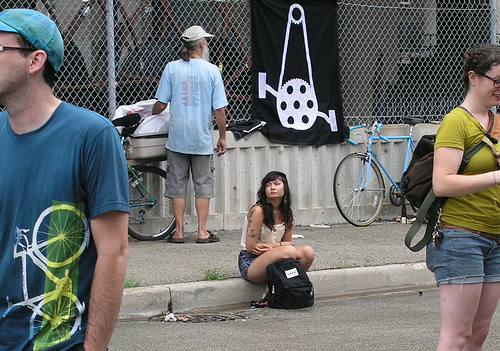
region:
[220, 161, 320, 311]
woman sitting on a curb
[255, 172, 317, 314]
black backpack in front of woman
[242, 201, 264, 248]
tattoos on woman's arm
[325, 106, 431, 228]
blue bicycle leaning against wall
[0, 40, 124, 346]
bicycle design on man's shirt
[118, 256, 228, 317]
weeds growing next to curb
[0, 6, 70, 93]
man wearing a blue cap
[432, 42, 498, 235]
woman wearing a green shirt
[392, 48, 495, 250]
woman wearing a backpack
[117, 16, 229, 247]
older man standing beside a bicycle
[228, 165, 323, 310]
woman sitting on curb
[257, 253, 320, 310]
black bag on street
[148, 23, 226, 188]
back of standing man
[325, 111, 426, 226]
blue bike against wall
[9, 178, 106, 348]
white bike on tee shirt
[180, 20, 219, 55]
hat on man's head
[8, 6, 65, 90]
blue hat on man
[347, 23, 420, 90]
metal of chain link fence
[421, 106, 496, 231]
green short sleeved shirt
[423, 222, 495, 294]
cut off blue jeans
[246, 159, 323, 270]
a person in the picture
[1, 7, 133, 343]
a person in the picture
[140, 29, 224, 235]
a person in the picture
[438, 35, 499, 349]
a person in the picture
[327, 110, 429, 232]
a bike in the picture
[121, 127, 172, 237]
a bike in the picture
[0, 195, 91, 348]
a bike in the picture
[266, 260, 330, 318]
a black bag in the picture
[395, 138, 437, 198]
a black bag in the picture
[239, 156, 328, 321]
a girl is seeing something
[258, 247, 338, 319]
a black colour back kept on the road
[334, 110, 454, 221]
a cycle parked in the side walk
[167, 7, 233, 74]
a hat on the man's head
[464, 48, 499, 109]
a lady wearing specks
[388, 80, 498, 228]
a lady holding back bag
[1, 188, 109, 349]
a cycle picture in the man's t-shirt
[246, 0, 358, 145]
a cloth hanging on the net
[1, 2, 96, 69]
a blue colour cap on the man's head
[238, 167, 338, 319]
a girl is sitting in the corner of the road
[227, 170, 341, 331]
girl sitting on street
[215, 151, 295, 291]
girl sitting on street